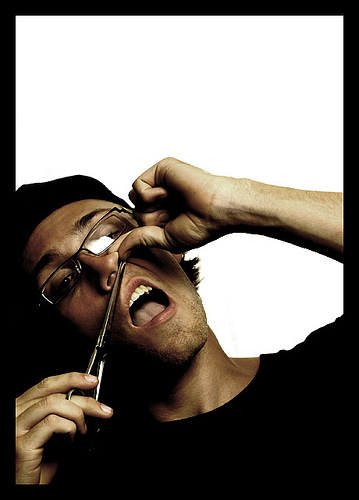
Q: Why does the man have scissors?
A: To clip nose hairs.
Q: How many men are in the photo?
A: One.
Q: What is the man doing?
A: Clipping nose hairs.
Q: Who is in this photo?
A: A man.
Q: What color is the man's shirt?
A: Black.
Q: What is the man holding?
A: Scissors.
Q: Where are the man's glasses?
A: On his eyes.